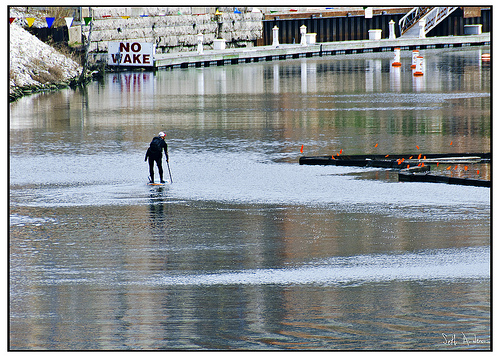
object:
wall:
[98, 10, 210, 35]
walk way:
[133, 28, 485, 65]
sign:
[104, 43, 160, 65]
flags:
[462, 160, 471, 175]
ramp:
[390, 4, 449, 37]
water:
[4, 133, 300, 351]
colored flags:
[11, 13, 22, 25]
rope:
[9, 10, 325, 26]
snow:
[14, 38, 39, 52]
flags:
[213, 7, 224, 20]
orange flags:
[403, 159, 414, 171]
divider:
[295, 152, 492, 195]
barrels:
[391, 46, 404, 67]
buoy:
[298, 141, 305, 153]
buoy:
[331, 150, 336, 159]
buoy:
[373, 140, 380, 148]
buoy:
[413, 142, 420, 149]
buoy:
[434, 160, 441, 167]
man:
[136, 124, 172, 190]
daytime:
[5, 0, 487, 345]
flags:
[157, 8, 169, 20]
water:
[153, 60, 478, 151]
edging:
[95, 38, 492, 73]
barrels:
[416, 55, 426, 77]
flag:
[298, 144, 307, 157]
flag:
[326, 152, 337, 160]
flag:
[370, 137, 381, 152]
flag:
[473, 167, 483, 177]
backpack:
[148, 134, 163, 154]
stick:
[166, 159, 174, 181]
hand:
[164, 153, 170, 161]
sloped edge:
[8, 22, 83, 87]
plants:
[14, 85, 23, 96]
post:
[270, 24, 279, 47]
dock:
[153, 32, 490, 70]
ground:
[16, 39, 36, 58]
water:
[302, 183, 486, 351]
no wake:
[109, 39, 159, 73]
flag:
[409, 155, 415, 159]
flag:
[328, 152, 337, 161]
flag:
[444, 164, 451, 172]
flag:
[405, 164, 410, 170]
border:
[311, 153, 374, 168]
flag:
[57, 14, 74, 30]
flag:
[39, 16, 56, 29]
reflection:
[131, 178, 191, 235]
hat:
[155, 132, 166, 141]